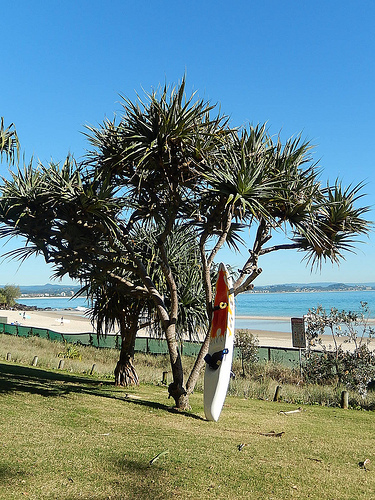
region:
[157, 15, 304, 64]
this is the sky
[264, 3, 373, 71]
the sky is blue in color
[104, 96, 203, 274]
this is a tree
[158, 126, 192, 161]
the leaves are green in color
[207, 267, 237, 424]
this is a surfboard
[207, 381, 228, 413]
the board is white in color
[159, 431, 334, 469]
this is a grass area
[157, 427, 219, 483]
the grass is green in color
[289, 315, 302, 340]
this is a post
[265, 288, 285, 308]
this is a water body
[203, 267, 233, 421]
A kayak by a tree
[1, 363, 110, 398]
A shadow on the ground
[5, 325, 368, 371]
A fence in front of the beach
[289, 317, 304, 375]
A sign by the fence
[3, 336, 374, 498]
A grassy field in front of the beach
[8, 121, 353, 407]
A tree in the grassy field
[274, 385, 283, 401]
A wooden post sticking out of the ground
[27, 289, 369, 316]
Water at the beach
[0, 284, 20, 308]
A tree on the beach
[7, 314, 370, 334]
Sand by the water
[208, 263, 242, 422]
kayak is red and white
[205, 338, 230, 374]
kayak seat is black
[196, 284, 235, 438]
kayak placed vertically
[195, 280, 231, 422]
kayak leaning on tree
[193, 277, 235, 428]
end of kayak on ground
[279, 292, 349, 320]
ocean water is blue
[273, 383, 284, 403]
fence post made of wood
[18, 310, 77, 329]
surfers walking on beach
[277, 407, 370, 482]
branches laying on ground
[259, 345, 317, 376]
green fence by beach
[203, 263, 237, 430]
a boat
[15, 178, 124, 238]
green leaves on the tree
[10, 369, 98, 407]
a shadow on the grass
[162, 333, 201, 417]
a tree trunk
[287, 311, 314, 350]
a sign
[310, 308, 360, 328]
flowers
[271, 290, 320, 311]
the ocean water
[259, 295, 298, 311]
water is light blue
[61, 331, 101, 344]
a green fence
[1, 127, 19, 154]
leaves of a palm tree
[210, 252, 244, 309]
the kayak is leaning on the tree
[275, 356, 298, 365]
the fence is green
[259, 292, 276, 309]
the water is teal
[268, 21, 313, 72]
the sky is baby blue in color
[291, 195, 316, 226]
the leaves are dark green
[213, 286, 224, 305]
the kayak is orange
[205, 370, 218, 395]
the kayak is white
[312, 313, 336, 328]
the leaves are dying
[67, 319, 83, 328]
the sand is tan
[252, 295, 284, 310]
the water has waves